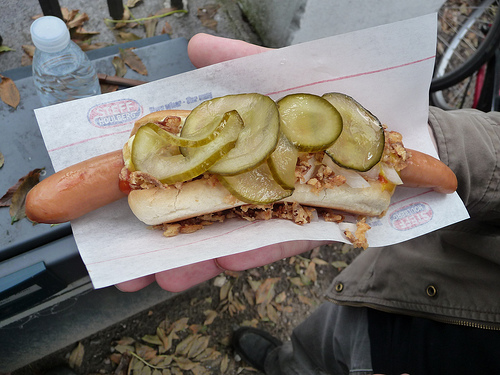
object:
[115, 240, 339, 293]
finger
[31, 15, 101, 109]
water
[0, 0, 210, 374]
table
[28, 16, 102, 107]
water bottle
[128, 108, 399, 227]
bun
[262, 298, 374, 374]
pants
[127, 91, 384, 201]
pickles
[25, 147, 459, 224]
hot dog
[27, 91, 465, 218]
sandwich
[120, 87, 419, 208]
pickels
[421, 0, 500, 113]
wheels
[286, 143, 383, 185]
floor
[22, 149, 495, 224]
sausage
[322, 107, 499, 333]
jacket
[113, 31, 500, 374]
person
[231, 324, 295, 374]
black shoes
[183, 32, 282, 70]
thumb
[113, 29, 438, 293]
hand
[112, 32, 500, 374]
man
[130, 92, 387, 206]
cucumbers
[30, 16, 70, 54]
cap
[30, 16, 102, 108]
bottle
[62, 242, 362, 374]
leaves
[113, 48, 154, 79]
leaves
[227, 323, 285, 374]
shoe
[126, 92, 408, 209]
toppings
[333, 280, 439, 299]
buttons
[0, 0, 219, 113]
leaves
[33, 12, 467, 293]
paper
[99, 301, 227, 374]
ground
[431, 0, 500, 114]
bike